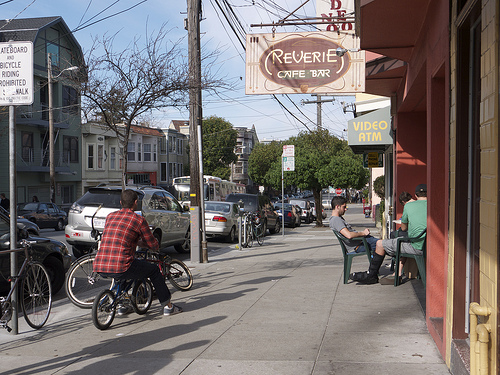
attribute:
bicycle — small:
[90, 245, 159, 334]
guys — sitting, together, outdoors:
[315, 186, 428, 276]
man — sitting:
[350, 179, 431, 288]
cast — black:
[345, 251, 384, 284]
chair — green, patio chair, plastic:
[385, 232, 429, 284]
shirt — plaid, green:
[397, 197, 429, 249]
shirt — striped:
[92, 208, 161, 274]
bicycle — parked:
[1, 239, 54, 334]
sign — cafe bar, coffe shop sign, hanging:
[247, 27, 367, 95]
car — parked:
[200, 197, 248, 244]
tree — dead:
[49, 49, 172, 194]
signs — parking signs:
[278, 141, 304, 172]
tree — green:
[251, 128, 369, 229]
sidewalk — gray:
[1, 217, 437, 374]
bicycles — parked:
[1, 234, 194, 346]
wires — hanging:
[214, 0, 319, 132]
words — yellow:
[352, 118, 390, 142]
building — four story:
[1, 13, 93, 217]